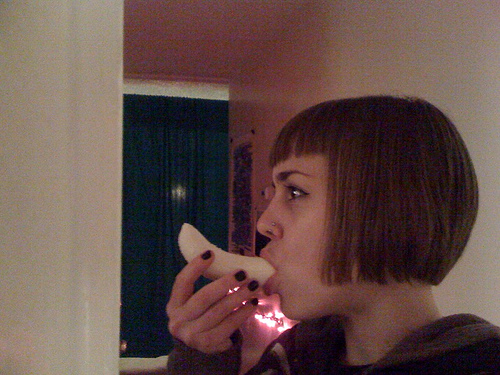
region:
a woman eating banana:
[175, 228, 282, 303]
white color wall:
[285, 19, 480, 94]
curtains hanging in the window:
[141, 108, 230, 214]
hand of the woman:
[163, 255, 270, 369]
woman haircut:
[263, 93, 473, 290]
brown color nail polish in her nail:
[193, 252, 258, 321]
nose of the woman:
[254, 206, 289, 253]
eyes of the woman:
[277, 173, 317, 205]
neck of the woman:
[311, 272, 473, 374]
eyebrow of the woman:
[271, 165, 321, 182]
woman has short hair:
[161, 70, 491, 370]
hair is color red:
[166, 80, 493, 355]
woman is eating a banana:
[146, 77, 497, 371]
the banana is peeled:
[168, 219, 279, 294]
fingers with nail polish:
[186, 245, 266, 321]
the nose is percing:
[253, 188, 288, 242]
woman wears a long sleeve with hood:
[145, 82, 498, 374]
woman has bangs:
[225, 83, 496, 328]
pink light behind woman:
[159, 85, 489, 362]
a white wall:
[0, 3, 120, 373]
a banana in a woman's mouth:
[177, 222, 278, 288]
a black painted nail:
[198, 248, 212, 259]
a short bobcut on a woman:
[264, 93, 475, 286]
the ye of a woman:
[285, 184, 312, 202]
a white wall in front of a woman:
[0, 2, 127, 373]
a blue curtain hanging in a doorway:
[121, 93, 235, 360]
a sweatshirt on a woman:
[163, 306, 496, 371]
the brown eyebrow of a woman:
[271, 165, 308, 180]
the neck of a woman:
[337, 277, 438, 367]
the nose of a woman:
[256, 194, 281, 240]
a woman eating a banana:
[165, 125, 383, 319]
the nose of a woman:
[251, 198, 294, 256]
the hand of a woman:
[151, 239, 297, 353]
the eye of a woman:
[274, 169, 323, 215]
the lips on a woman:
[251, 230, 286, 308]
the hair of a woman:
[227, 48, 464, 319]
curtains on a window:
[103, 60, 275, 330]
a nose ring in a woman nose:
[262, 217, 289, 240]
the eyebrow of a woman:
[268, 157, 328, 186]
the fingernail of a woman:
[189, 245, 217, 277]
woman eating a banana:
[163, 88, 498, 365]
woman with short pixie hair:
[252, 86, 494, 331]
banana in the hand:
[172, 215, 272, 285]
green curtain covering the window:
[124, 90, 228, 212]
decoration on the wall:
[225, 129, 255, 251]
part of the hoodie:
[407, 323, 491, 362]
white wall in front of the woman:
[23, 18, 105, 263]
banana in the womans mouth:
[168, 215, 278, 287]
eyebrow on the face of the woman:
[270, 164, 309, 181]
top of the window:
[122, 80, 234, 97]